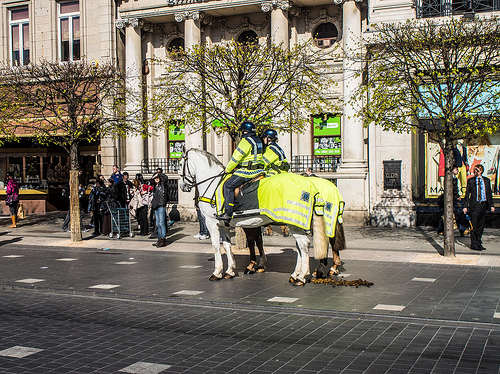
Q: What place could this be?
A: It is a street.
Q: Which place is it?
A: It is a street.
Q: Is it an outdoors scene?
A: Yes, it is outdoors.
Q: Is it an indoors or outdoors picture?
A: It is outdoors.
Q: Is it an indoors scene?
A: No, it is outdoors.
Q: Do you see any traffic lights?
A: No, there are no traffic lights.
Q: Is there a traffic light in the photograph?
A: No, there are no traffic lights.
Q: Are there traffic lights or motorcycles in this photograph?
A: No, there are no traffic lights or motorcycles.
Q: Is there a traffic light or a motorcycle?
A: No, there are no traffic lights or motorcycles.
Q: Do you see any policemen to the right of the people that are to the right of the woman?
A: Yes, there is a policeman to the right of the people.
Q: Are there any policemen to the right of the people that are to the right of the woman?
A: Yes, there is a policeman to the right of the people.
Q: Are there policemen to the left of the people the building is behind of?
A: No, the policeman is to the right of the people.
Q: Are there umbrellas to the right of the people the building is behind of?
A: No, there is a policeman to the right of the people.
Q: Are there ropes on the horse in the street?
A: No, there is a policeman on the horse.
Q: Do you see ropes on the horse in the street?
A: No, there is a policeman on the horse.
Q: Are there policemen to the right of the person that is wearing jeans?
A: Yes, there is a policeman to the right of the person.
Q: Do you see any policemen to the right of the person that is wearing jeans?
A: Yes, there is a policeman to the right of the person.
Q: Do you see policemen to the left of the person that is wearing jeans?
A: No, the policeman is to the right of the person.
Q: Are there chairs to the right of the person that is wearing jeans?
A: No, there is a policeman to the right of the person.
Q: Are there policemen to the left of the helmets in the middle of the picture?
A: Yes, there is a policeman to the left of the helmets.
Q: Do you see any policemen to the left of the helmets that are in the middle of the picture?
A: Yes, there is a policeman to the left of the helmets.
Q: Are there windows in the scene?
A: Yes, there is a window.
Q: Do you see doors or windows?
A: Yes, there is a window.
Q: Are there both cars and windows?
A: No, there is a window but no cars.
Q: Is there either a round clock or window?
A: Yes, there is a round window.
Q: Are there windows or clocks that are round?
A: Yes, the window is round.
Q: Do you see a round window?
A: Yes, there is a round window.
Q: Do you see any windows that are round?
A: Yes, there is a window that is round.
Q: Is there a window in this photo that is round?
A: Yes, there is a window that is round.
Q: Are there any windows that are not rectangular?
A: Yes, there is a round window.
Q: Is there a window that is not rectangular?
A: Yes, there is a round window.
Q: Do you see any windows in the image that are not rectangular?
A: Yes, there is a round window.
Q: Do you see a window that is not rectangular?
A: Yes, there is a round window.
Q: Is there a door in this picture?
A: No, there are no doors.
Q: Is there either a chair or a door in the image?
A: No, there are no doors or chairs.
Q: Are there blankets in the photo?
A: Yes, there is a blanket.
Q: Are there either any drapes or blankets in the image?
A: Yes, there is a blanket.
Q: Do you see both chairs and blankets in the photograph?
A: No, there is a blanket but no chairs.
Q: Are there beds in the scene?
A: No, there are no beds.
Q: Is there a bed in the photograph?
A: No, there are no beds.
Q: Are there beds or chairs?
A: No, there are no beds or chairs.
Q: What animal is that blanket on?
A: The blanket is on the horse.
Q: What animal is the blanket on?
A: The blanket is on the horse.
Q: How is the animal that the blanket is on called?
A: The animal is a horse.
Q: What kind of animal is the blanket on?
A: The blanket is on the horse.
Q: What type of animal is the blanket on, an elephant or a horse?
A: The blanket is on a horse.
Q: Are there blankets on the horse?
A: Yes, there is a blanket on the horse.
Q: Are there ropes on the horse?
A: No, there is a blanket on the horse.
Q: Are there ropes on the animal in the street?
A: No, there is a blanket on the horse.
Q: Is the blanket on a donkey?
A: No, the blanket is on the horse.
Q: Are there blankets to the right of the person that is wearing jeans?
A: Yes, there is a blanket to the right of the person.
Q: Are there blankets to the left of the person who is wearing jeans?
A: No, the blanket is to the right of the person.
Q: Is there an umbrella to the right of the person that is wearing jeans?
A: No, there is a blanket to the right of the person.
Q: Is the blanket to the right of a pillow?
A: No, the blanket is to the right of the person.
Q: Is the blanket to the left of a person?
A: No, the blanket is to the right of a person.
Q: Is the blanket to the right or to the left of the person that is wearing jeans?
A: The blanket is to the right of the person.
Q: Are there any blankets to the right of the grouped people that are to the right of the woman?
A: Yes, there is a blanket to the right of the people.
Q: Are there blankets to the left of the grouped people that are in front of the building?
A: No, the blanket is to the right of the people.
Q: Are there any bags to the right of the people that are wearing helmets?
A: No, there is a blanket to the right of the people.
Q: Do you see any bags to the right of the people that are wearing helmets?
A: No, there is a blanket to the right of the people.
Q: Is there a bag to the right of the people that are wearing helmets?
A: No, there is a blanket to the right of the people.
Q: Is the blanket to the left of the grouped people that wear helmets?
A: No, the blanket is to the right of the people.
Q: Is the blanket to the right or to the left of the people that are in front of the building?
A: The blanket is to the right of the people.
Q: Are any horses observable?
A: Yes, there is a horse.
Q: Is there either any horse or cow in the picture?
A: Yes, there is a horse.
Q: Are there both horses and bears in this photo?
A: No, there is a horse but no bears.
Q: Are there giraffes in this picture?
A: No, there are no giraffes.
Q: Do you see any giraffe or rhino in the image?
A: No, there are no giraffes or rhinos.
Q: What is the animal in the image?
A: The animal is a horse.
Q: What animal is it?
A: The animal is a horse.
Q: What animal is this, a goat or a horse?
A: This is a horse.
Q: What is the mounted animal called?
A: The animal is a horse.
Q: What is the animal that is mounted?
A: The animal is a horse.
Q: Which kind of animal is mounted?
A: The animal is a horse.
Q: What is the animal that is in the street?
A: The animal is a horse.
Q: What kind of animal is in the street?
A: The animal is a horse.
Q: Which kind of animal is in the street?
A: The animal is a horse.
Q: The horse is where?
A: The horse is in the street.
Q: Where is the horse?
A: The horse is in the street.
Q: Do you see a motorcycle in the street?
A: No, there is a horse in the street.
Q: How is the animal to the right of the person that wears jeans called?
A: The animal is a horse.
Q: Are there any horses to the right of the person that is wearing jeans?
A: Yes, there is a horse to the right of the person.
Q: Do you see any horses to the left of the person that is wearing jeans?
A: No, the horse is to the right of the person.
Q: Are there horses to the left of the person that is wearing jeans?
A: No, the horse is to the right of the person.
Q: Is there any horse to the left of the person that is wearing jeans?
A: No, the horse is to the right of the person.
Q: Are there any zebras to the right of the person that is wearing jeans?
A: No, there is a horse to the right of the person.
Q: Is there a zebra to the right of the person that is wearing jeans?
A: No, there is a horse to the right of the person.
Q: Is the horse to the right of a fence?
A: No, the horse is to the right of a person.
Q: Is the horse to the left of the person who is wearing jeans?
A: No, the horse is to the right of the person.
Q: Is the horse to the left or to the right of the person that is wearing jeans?
A: The horse is to the right of the person.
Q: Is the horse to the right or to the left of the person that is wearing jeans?
A: The horse is to the right of the person.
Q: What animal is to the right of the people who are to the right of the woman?
A: The animal is a horse.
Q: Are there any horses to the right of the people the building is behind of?
A: Yes, there is a horse to the right of the people.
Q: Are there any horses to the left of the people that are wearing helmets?
A: No, the horse is to the right of the people.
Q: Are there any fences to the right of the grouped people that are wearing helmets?
A: No, there is a horse to the right of the people.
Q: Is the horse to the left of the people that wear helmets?
A: No, the horse is to the right of the people.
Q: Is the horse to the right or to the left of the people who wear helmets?
A: The horse is to the right of the people.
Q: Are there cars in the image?
A: No, there are no cars.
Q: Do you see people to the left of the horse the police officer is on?
A: Yes, there is a person to the left of the horse.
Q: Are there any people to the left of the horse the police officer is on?
A: Yes, there is a person to the left of the horse.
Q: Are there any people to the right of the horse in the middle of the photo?
A: No, the person is to the left of the horse.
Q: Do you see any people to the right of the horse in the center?
A: No, the person is to the left of the horse.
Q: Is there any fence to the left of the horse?
A: No, there is a person to the left of the horse.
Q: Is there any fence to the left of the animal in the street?
A: No, there is a person to the left of the horse.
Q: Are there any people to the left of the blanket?
A: Yes, there is a person to the left of the blanket.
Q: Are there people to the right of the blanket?
A: No, the person is to the left of the blanket.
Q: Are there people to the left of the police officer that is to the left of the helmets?
A: Yes, there is a person to the left of the police officer.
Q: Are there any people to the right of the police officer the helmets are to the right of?
A: No, the person is to the left of the policeman.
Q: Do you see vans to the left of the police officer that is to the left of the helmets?
A: No, there is a person to the left of the police officer.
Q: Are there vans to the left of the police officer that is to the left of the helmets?
A: No, there is a person to the left of the police officer.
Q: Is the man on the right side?
A: Yes, the man is on the right of the image.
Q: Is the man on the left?
A: No, the man is on the right of the image.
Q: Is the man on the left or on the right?
A: The man is on the right of the image.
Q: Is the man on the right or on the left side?
A: The man is on the right of the image.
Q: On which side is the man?
A: The man is on the right of the image.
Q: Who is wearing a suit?
A: The man is wearing a suit.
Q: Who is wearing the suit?
A: The man is wearing a suit.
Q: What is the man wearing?
A: The man is wearing a suit.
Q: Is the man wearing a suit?
A: Yes, the man is wearing a suit.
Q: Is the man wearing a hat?
A: No, the man is wearing a suit.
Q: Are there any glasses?
A: No, there are no glasses.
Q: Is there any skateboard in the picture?
A: No, there are no skateboards.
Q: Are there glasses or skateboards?
A: No, there are no skateboards or glasses.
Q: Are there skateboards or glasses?
A: No, there are no skateboards or glasses.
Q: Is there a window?
A: Yes, there is a window.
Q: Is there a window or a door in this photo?
A: Yes, there is a window.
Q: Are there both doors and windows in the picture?
A: No, there is a window but no doors.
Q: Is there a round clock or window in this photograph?
A: Yes, there is a round window.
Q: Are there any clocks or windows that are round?
A: Yes, the window is round.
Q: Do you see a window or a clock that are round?
A: Yes, the window is round.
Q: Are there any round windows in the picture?
A: Yes, there is a round window.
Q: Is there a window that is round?
A: Yes, there is a window that is round.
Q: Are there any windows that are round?
A: Yes, there is a window that is round.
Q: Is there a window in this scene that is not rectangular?
A: Yes, there is a round window.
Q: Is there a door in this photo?
A: No, there are no doors.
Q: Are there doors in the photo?
A: No, there are no doors.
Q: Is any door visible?
A: No, there are no doors.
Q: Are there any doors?
A: No, there are no doors.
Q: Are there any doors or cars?
A: No, there are no doors or cars.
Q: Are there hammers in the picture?
A: No, there are no hammers.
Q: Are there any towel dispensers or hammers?
A: No, there are no hammers or towel dispensers.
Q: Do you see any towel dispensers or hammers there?
A: No, there are no hammers or towel dispensers.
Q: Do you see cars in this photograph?
A: No, there are no cars.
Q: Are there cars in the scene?
A: No, there are no cars.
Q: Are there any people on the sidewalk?
A: Yes, there are people on the sidewalk.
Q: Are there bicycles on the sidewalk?
A: No, there are people on the sidewalk.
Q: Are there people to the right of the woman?
A: Yes, there are people to the right of the woman.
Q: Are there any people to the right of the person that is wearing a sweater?
A: Yes, there are people to the right of the woman.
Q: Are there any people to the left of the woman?
A: No, the people are to the right of the woman.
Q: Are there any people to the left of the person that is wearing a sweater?
A: No, the people are to the right of the woman.